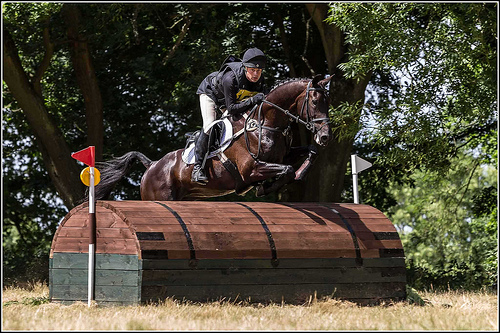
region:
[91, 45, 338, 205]
a person on a horse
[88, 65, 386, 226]
a horse jumping barrel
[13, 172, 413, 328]
a brown and black barrel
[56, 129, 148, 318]
a red flag on pole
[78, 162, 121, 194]
a small yellow circle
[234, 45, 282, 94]
a hat on the head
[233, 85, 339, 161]
a black leash on horse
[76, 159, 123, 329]
a white pole with red flag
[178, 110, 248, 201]
black knee high boots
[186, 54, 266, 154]
a black shirt and white pants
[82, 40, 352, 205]
Horse jumping brown obstacle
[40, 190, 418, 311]
brown and black wooden obstacle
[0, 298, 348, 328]
Dry yellowed grass on course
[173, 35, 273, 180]
Horseback rider in mid jump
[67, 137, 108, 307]
red flag on obstacle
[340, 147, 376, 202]
White flag on obstable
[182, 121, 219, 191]
Black Horseback riding boot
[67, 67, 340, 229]
Horse in mid air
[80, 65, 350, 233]
Jumping gleaming brown horse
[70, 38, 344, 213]
Horse and rider riding.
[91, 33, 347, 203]
person on a horse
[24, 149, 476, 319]
obstacle horse jumps over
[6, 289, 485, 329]
brown grass on the ground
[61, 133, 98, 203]
flag on the obstacle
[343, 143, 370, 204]
flag on the obstacle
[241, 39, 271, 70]
hat on person on horse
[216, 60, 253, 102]
jacket on the person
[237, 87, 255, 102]
number on the rider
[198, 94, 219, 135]
pants on the rider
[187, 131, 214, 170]
boots on the rider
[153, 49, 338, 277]
a horse jumping a obsticle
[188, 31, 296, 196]
a man riding a horse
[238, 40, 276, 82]
a man wearing a black hat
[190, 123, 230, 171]
a man wearing black boots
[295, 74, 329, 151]
a horse wearing a bridle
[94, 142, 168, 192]
a horse with a long tail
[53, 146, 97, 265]
a small red flag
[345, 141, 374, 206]
a small white flag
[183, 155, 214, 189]
a man's foot in a stirrup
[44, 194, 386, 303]
a wood obsticle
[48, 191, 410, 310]
A wooden obstacle in the grass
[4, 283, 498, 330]
Brown grass on the ground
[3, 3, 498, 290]
Branches of bright, green leaves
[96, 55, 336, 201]
A person riding a dark brown horse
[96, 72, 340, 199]
A horse leaping an obstacle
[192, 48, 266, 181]
A person in black on top of a horse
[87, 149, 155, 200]
The hair of a horse's tail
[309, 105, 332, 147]
The snout of a horse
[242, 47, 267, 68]
Black helmet on a horse rider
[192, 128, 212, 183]
A jockey's black boot